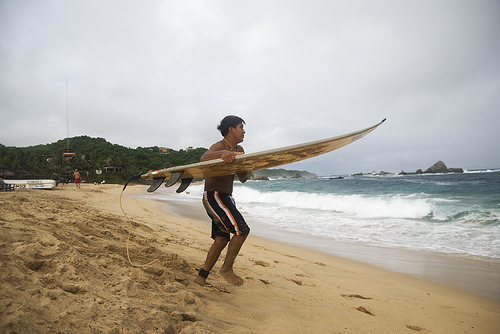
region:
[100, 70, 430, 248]
man holding a surfboard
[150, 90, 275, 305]
man wearing a short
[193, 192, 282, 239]
the short is black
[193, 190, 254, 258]
the short is dirty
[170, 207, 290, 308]
the man has two legs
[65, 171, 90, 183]
the shorts is red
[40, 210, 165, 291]
the sand is brown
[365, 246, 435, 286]
the sand is wet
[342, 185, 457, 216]
the water is blue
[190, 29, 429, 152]
the sky is gray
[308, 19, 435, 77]
part of a cloudy sky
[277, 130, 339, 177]
part of a swimming board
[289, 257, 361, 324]
part of a sandy beach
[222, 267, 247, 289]
right foot of the boy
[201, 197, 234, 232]
part of a black short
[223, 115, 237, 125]
hair of a boy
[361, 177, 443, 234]
part of water waves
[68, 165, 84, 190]
a man in red pants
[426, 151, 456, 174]
section of a rock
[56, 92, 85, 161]
part of a tall post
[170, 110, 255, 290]
man at beach holding a surfboard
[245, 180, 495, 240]
sea waves crushing unto beach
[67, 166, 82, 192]
person in red pants running on beach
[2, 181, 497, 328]
sandy clean beach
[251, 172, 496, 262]
sea continue to produce waves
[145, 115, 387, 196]
surfboard in man's hand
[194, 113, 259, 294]
man carrying surfboard to the sea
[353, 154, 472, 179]
rocks protruding from sea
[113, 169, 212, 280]
surfboard leash string tied to man's foot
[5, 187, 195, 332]
disturbed beach sand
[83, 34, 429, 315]
Picture of man going to surf.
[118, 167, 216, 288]
Leash for surfboard.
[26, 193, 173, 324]
Footprints and tracks in the sand.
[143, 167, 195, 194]
Three fins on surfboard.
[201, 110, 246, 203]
Man with dark hair.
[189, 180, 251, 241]
A pair of striped bottoms.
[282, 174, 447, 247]
White waves in the ocean.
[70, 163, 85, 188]
Person in red shorts.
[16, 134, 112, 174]
Green trees in the background.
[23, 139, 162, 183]
Hills in the background.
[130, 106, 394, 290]
young man carrying surfboard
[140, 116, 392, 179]
surfboard being carried to water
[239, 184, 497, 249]
waves breaking on shore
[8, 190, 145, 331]
beach sand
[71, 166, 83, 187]
person walking in the distance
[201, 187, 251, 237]
black swim trunks with white and orange stripes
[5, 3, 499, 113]
cloudy skies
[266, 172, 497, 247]
ocean with waves breaking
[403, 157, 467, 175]
hill in the distance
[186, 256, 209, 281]
strap from surfboard on young man's ankle